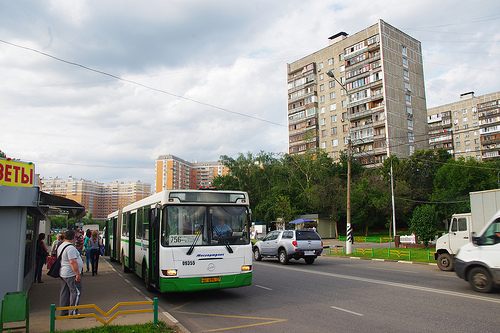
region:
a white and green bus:
[107, 193, 252, 291]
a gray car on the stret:
[254, 229, 324, 261]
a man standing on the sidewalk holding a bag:
[50, 230, 81, 315]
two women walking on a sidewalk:
[82, 228, 105, 275]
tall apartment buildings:
[286, 21, 498, 166]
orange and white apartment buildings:
[39, 155, 274, 216]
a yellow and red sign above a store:
[1, 158, 38, 187]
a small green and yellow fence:
[48, 297, 159, 331]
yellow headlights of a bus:
[163, 262, 255, 275]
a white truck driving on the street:
[433, 190, 498, 270]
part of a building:
[198, 176, 202, 182]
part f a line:
[252, 310, 270, 329]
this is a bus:
[136, 187, 255, 287]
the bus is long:
[126, 187, 256, 280]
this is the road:
[289, 269, 370, 331]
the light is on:
[237, 261, 257, 273]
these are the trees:
[416, 157, 463, 209]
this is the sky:
[184, 7, 269, 60]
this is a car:
[261, 225, 324, 265]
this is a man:
[52, 225, 86, 300]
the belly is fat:
[72, 255, 86, 274]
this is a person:
[52, 223, 85, 314]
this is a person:
[88, 229, 100, 275]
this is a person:
[33, 229, 48, 283]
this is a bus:
[158, 186, 251, 290]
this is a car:
[253, 222, 324, 260]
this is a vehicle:
[451, 201, 499, 296]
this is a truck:
[434, 185, 496, 271]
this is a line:
[327, 295, 367, 320]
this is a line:
[189, 309, 246, 320]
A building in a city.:
[286, 17, 430, 182]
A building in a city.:
[153, 152, 265, 195]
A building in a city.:
[38, 176, 152, 217]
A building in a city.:
[426, 88, 499, 164]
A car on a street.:
[253, 227, 323, 264]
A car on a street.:
[457, 208, 499, 295]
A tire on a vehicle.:
[253, 247, 262, 259]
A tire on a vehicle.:
[278, 247, 288, 264]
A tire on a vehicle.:
[436, 251, 453, 273]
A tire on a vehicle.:
[466, 266, 495, 293]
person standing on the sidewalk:
[57, 228, 82, 313]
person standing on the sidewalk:
[86, 227, 101, 272]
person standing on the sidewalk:
[45, 233, 61, 259]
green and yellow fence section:
[386, 248, 411, 258]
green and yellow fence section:
[352, 245, 374, 256]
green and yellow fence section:
[427, 248, 433, 259]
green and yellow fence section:
[48, 297, 158, 329]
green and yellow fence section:
[329, 246, 343, 251]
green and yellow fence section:
[363, 234, 381, 241]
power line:
[3, 39, 287, 129]